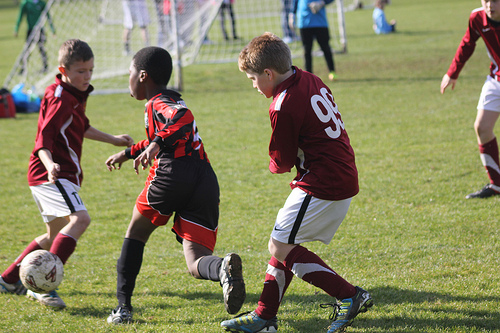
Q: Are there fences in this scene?
A: No, there are no fences.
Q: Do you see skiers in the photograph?
A: No, there are no skiers.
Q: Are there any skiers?
A: No, there are no skiers.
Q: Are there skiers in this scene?
A: No, there are no skiers.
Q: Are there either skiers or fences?
A: No, there are no skiers or fences.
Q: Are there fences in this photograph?
A: No, there are no fences.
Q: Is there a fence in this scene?
A: No, there are no fences.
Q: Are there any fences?
A: No, there are no fences.